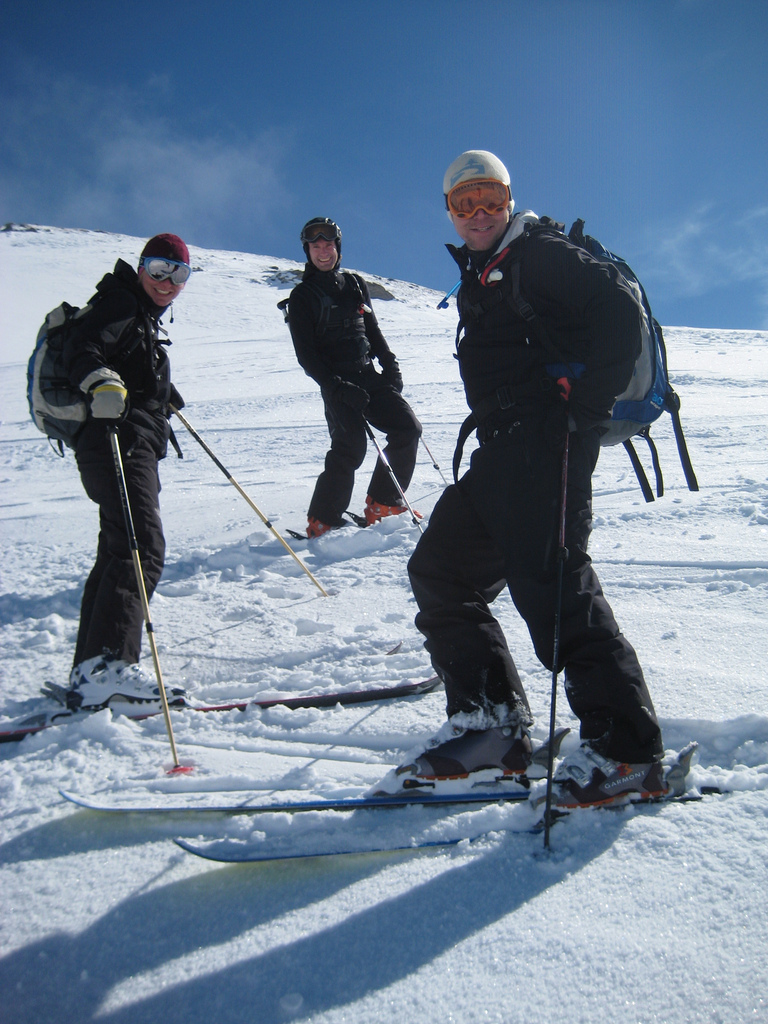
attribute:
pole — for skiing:
[527, 396, 584, 877]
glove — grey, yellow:
[75, 343, 160, 417]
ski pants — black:
[69, 444, 172, 656]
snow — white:
[9, 220, 761, 1022]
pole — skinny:
[533, 448, 604, 802]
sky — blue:
[541, 96, 624, 189]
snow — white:
[541, 842, 742, 967]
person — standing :
[402, 131, 691, 806]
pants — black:
[60, 469, 228, 848]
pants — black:
[78, 425, 152, 665]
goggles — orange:
[448, 182, 526, 229]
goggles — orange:
[440, 190, 514, 230]